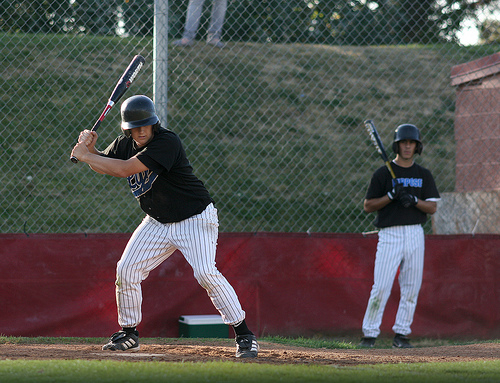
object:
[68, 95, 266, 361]
man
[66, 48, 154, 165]
baseball bat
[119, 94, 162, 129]
helmet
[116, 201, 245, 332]
jersey pants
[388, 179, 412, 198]
gloves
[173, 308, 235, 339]
chest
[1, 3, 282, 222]
fence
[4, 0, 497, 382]
ballpark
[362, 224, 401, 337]
legs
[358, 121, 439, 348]
spectator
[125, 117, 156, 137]
eyes down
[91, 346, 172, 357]
pad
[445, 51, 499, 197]
small building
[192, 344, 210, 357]
dirt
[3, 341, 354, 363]
batter box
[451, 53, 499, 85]
roof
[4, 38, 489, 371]
baseball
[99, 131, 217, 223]
shirt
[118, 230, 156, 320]
stripes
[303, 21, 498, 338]
background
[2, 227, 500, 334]
trim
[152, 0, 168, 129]
pole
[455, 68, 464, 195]
edge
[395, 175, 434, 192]
writing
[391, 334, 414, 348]
shoes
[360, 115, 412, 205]
baseball bat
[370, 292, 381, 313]
grass stain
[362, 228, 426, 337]
pants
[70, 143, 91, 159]
hand